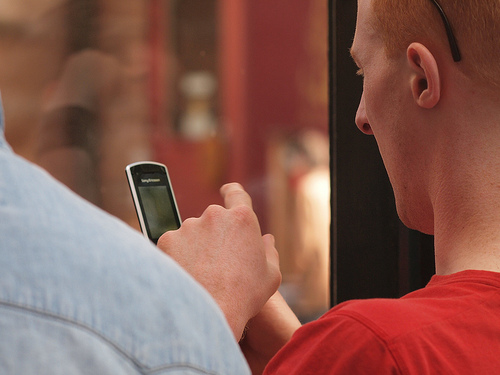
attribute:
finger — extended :
[219, 178, 253, 211]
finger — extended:
[218, 180, 251, 207]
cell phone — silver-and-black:
[88, 133, 220, 258]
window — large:
[3, 0, 336, 374]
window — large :
[0, 1, 331, 323]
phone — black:
[121, 157, 181, 247]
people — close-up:
[146, 41, 497, 351]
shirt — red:
[261, 270, 498, 374]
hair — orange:
[373, 0, 499, 92]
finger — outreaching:
[220, 170, 256, 205]